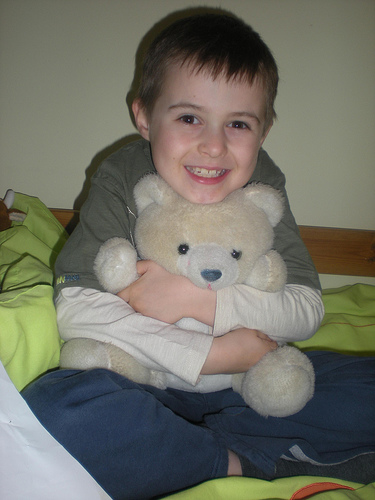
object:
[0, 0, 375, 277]
headboard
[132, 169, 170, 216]
ear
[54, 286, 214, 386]
sleeves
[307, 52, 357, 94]
ground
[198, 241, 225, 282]
nose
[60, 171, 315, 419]
bear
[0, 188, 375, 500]
bed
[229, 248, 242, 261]
eye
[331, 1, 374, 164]
wall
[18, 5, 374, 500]
boy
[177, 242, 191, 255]
eyes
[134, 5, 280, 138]
brown hair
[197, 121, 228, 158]
nose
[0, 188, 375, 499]
sheet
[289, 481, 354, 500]
edge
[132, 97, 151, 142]
ear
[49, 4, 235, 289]
shadow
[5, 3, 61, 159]
wall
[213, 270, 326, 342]
sleeves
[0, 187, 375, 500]
blanket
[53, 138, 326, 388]
shirt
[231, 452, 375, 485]
sock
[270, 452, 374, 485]
foot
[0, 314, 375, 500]
cover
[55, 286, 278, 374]
arm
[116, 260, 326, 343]
arm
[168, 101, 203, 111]
eyebrow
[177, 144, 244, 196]
smile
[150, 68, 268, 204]
face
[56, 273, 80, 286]
logo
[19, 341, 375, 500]
pants